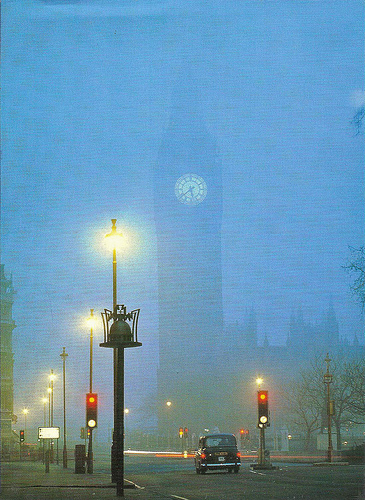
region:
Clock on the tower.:
[134, 102, 321, 294]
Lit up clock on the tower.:
[175, 165, 224, 220]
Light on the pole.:
[238, 376, 291, 478]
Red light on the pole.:
[245, 374, 289, 425]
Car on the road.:
[183, 416, 280, 494]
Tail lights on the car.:
[191, 438, 297, 477]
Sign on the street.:
[25, 415, 88, 479]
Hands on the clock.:
[158, 154, 228, 215]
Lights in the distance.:
[145, 392, 212, 465]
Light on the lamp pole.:
[77, 194, 161, 300]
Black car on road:
[188, 430, 244, 475]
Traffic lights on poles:
[81, 386, 281, 433]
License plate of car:
[213, 449, 228, 461]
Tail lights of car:
[198, 448, 242, 462]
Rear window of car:
[205, 434, 237, 449]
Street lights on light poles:
[31, 219, 129, 418]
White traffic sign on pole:
[32, 422, 63, 440]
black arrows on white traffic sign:
[38, 428, 43, 438]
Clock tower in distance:
[150, 56, 231, 376]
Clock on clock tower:
[169, 168, 210, 210]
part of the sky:
[282, 255, 303, 283]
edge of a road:
[125, 466, 138, 485]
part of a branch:
[339, 396, 345, 410]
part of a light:
[259, 389, 265, 396]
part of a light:
[254, 416, 274, 430]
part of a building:
[5, 383, 16, 411]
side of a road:
[147, 473, 158, 489]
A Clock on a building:
[152, 157, 226, 232]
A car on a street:
[191, 428, 245, 479]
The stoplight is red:
[246, 376, 279, 483]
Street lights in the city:
[32, 298, 106, 476]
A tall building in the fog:
[144, 45, 238, 426]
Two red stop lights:
[75, 374, 285, 450]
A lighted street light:
[93, 205, 143, 498]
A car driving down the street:
[128, 411, 256, 488]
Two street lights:
[71, 210, 132, 487]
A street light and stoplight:
[246, 369, 285, 475]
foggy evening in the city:
[19, 63, 354, 472]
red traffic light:
[78, 385, 98, 449]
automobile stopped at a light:
[182, 374, 277, 474]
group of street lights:
[17, 357, 57, 418]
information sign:
[33, 418, 55, 467]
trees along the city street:
[277, 347, 357, 453]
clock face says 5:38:
[169, 167, 204, 208]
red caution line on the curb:
[149, 448, 191, 456]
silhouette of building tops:
[238, 287, 358, 347]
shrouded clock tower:
[136, 67, 232, 301]